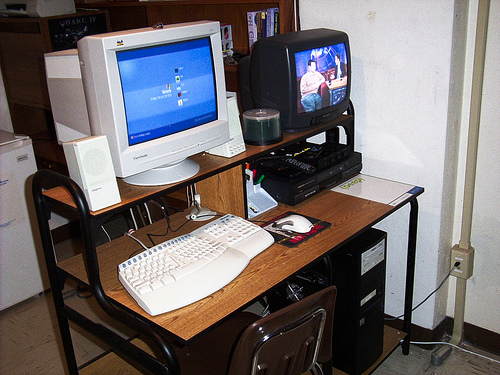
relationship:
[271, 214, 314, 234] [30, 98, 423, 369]
mouse on desk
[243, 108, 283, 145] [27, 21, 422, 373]
cd holder on desk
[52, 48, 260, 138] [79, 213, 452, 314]
computer on desk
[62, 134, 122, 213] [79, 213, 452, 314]
speaker on desk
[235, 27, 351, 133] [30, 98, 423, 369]
t.v on desk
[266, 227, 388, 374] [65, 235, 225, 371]
computer under desk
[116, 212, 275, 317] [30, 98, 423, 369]
key board on desk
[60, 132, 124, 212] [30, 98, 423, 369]
speaker on desk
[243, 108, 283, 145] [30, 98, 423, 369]
cd holder on desk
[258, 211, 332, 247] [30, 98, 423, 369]
mouse pad on desk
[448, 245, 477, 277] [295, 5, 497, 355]
outlet on wall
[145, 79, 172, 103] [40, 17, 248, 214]
windows on computer